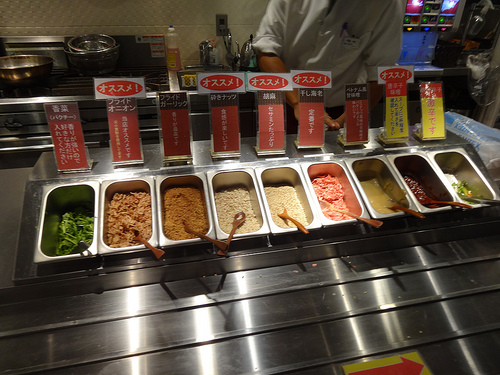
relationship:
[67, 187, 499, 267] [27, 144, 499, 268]
spoons in container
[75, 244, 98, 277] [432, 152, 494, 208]
spoon in container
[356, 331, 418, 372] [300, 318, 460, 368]
arrow on counter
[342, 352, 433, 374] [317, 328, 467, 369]
arrow on counter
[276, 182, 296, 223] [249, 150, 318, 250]
rice in container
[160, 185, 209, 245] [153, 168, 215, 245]
rice in container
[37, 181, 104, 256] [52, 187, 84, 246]
container of food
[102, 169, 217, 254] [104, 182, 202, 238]
containers of food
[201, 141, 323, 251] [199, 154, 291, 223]
container of food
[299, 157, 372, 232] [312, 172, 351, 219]
container of food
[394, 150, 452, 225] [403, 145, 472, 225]
container of food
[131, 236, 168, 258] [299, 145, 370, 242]
handle sticking out of container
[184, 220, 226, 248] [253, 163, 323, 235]
handle sticking out of container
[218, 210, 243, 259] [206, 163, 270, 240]
handle sticking out of container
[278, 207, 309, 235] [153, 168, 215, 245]
handle sticking out of container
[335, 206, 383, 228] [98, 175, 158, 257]
handle sticking out of container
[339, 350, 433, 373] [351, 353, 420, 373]
sticker with arrow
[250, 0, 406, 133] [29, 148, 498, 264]
man standing behind buffet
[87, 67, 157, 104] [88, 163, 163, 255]
label behind container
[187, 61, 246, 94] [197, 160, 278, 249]
label behind container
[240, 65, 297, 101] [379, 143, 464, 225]
label behind container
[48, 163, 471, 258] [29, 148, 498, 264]
good on a buffet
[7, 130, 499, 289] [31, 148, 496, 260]
container with food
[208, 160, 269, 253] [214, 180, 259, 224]
container with food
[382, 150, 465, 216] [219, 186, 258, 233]
container with food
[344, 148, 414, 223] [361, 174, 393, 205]
container with food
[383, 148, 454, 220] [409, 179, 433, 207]
metal container with food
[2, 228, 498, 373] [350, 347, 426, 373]
counter with red arrow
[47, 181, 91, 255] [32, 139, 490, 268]
condiments are in containers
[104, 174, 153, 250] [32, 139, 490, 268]
condiments are in containers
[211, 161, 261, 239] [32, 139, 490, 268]
condiments are in containers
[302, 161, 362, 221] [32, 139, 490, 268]
condiments are in containers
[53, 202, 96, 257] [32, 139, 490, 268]
condiment are in containers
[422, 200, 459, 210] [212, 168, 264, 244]
spoons are in container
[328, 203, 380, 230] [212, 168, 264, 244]
spoons are in container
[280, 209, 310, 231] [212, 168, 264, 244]
spoons are in container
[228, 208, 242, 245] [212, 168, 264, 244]
spoons are in container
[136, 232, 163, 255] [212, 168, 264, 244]
spoons are in container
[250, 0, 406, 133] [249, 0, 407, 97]
man wearing shirt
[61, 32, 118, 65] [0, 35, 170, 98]
metal on a stove top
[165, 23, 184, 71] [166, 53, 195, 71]
bottle of oil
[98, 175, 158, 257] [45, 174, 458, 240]
container of food